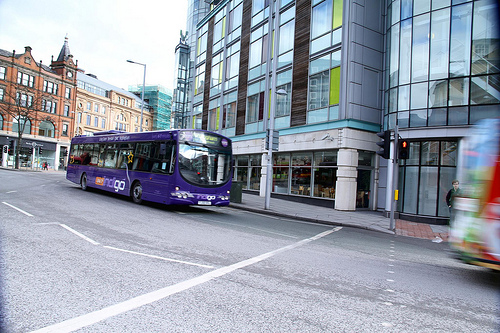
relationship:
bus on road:
[59, 126, 238, 212] [108, 217, 146, 237]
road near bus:
[108, 217, 146, 237] [59, 126, 238, 212]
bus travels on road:
[59, 126, 238, 212] [108, 217, 146, 237]